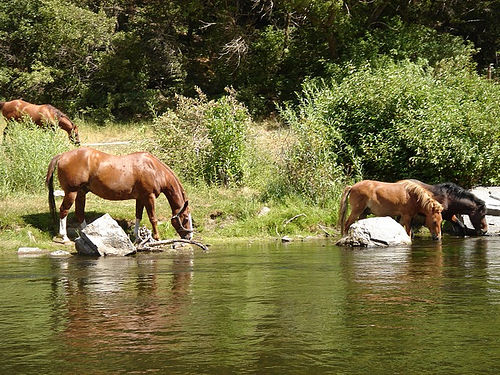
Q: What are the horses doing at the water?
A: Drinking.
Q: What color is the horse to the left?
A: Brown.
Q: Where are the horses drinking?
A: River.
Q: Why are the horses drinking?
A: Quench thirst.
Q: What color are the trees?
A: Green.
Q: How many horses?
A: Four.